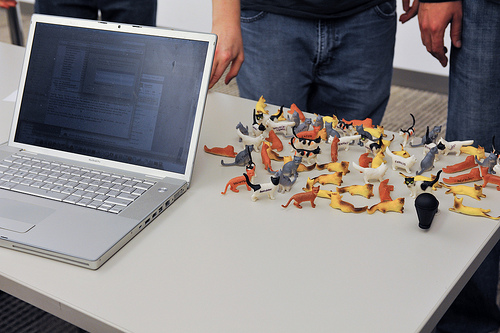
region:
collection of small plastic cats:
[203, 85, 496, 232]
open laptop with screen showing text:
[5, 5, 212, 280]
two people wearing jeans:
[207, 2, 492, 132]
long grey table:
[15, 25, 490, 325]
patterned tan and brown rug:
[390, 75, 446, 131]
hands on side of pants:
[211, 0, 462, 85]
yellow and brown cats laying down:
[325, 157, 375, 222]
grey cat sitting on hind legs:
[275, 152, 300, 187]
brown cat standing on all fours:
[277, 180, 320, 212]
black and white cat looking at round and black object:
[398, 160, 443, 235]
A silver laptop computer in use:
[0, 12, 219, 271]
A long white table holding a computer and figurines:
[1, 37, 498, 331]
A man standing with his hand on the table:
[191, 0, 391, 129]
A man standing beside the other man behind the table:
[402, 5, 499, 311]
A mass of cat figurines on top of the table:
[206, 82, 499, 228]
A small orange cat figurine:
[215, 161, 260, 198]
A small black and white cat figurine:
[236, 166, 285, 201]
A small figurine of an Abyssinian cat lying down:
[322, 188, 369, 218]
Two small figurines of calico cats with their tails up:
[283, 132, 323, 164]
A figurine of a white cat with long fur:
[228, 127, 272, 149]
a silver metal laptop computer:
[3, 11, 214, 274]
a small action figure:
[362, 176, 405, 218]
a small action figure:
[410, 192, 440, 231]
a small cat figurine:
[282, 184, 321, 211]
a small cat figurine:
[238, 170, 280, 202]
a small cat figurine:
[219, 141, 255, 168]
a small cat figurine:
[349, 161, 393, 185]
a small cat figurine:
[441, 191, 492, 222]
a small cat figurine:
[440, 175, 487, 201]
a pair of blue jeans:
[229, 0, 401, 120]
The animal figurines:
[206, 91, 498, 238]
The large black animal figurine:
[408, 190, 439, 232]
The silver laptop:
[0, 12, 218, 270]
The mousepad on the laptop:
[0, 193, 57, 236]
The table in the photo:
[0, 41, 498, 331]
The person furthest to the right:
[416, 1, 498, 332]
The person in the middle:
[201, 1, 417, 128]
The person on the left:
[0, 1, 158, 36]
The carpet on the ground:
[0, 5, 496, 332]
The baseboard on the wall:
[6, 0, 446, 95]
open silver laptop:
[2, 9, 218, 272]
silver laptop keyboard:
[3, 147, 158, 216]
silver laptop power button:
[156, 181, 170, 196]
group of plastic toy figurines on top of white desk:
[206, 108, 499, 236]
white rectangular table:
[2, 34, 497, 330]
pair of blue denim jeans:
[230, 8, 404, 126]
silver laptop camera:
[107, 23, 127, 33]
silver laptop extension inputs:
[131, 181, 193, 231]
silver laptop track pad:
[2, 191, 56, 226]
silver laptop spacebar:
[0, 213, 37, 233]